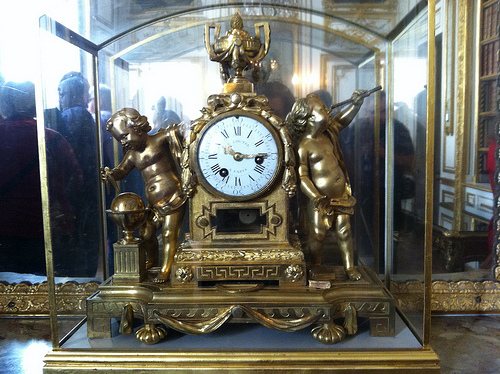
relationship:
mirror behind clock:
[9, 10, 481, 286] [97, 0, 403, 354]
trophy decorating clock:
[208, 5, 276, 90] [97, 0, 403, 354]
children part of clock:
[283, 86, 373, 282] [97, 0, 403, 354]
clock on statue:
[191, 109, 280, 208] [80, 11, 406, 346]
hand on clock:
[214, 140, 233, 154] [130, 28, 391, 342]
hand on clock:
[241, 150, 274, 166] [188, 107, 288, 203]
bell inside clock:
[231, 207, 268, 229] [130, 28, 391, 342]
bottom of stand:
[96, 281, 416, 343] [64, 235, 404, 345]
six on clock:
[229, 171, 247, 190] [188, 107, 288, 203]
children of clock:
[118, 119, 203, 267] [87, 35, 405, 349]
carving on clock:
[200, 20, 280, 79] [188, 107, 288, 203]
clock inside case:
[188, 107, 288, 203] [23, 0, 441, 372]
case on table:
[30, 0, 444, 374] [441, 312, 482, 361]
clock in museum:
[188, 107, 288, 203] [0, 2, 491, 365]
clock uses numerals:
[188, 107, 288, 203] [208, 125, 260, 176]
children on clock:
[113, 109, 203, 255] [115, 41, 399, 334]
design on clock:
[190, 254, 290, 277] [103, 20, 412, 343]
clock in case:
[188, 107, 288, 203] [40, 0, 433, 354]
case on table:
[23, 0, 441, 372] [441, 300, 479, 363]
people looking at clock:
[3, 79, 103, 247] [116, 37, 387, 318]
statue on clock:
[196, 16, 286, 81] [130, 22, 423, 348]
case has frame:
[23, 0, 441, 372] [415, 189, 455, 347]